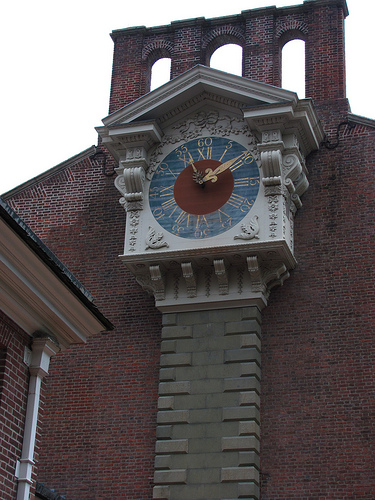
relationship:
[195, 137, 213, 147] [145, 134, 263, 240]
60 on clock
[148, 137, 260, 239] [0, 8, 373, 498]
clock on building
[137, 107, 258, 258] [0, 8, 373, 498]
clock on building